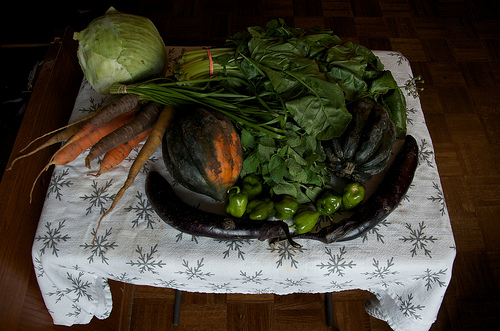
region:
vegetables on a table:
[21, 4, 456, 308]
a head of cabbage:
[62, 6, 187, 99]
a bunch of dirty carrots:
[0, 64, 227, 239]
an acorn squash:
[140, 87, 236, 212]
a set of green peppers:
[211, 168, 441, 248]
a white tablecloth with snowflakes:
[27, 12, 479, 329]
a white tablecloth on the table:
[30, 17, 496, 328]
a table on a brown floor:
[1, 8, 494, 313]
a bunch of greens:
[128, 22, 439, 147]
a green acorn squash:
[299, 83, 406, 186]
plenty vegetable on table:
[107, 88, 422, 259]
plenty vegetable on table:
[61, 2, 389, 307]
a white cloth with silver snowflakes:
[29, 7, 458, 321]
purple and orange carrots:
[28, 70, 178, 226]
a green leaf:
[260, 52, 346, 133]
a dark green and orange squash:
[170, 102, 245, 197]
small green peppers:
[288, 181, 366, 233]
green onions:
[113, 74, 300, 131]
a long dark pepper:
[313, 131, 426, 251]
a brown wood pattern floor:
[11, 17, 498, 327]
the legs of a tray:
[156, 282, 346, 329]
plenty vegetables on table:
[55, 4, 427, 245]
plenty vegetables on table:
[91, 107, 418, 272]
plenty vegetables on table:
[195, 101, 400, 241]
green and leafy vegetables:
[217, 49, 375, 194]